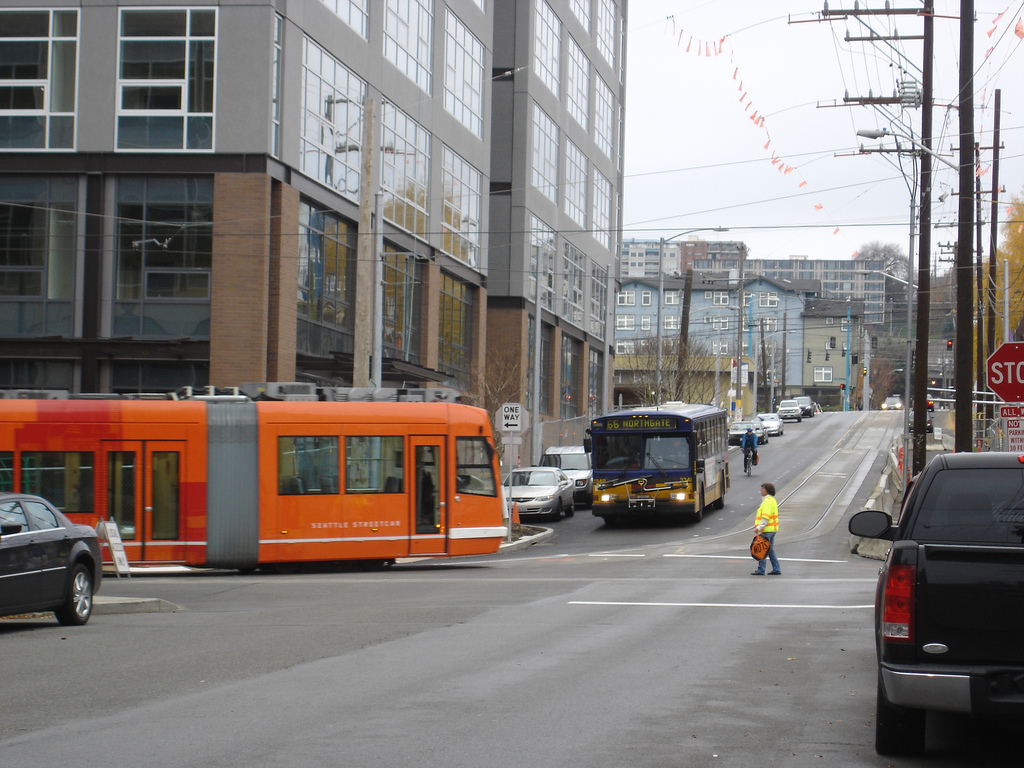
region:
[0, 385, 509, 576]
Orange bus is turning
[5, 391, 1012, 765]
Bus on the road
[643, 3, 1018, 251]
flags hanging from lines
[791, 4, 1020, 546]
Power lines on sidewalk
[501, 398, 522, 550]
A one way sign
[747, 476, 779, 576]
Peron wearing yellow and orange jacket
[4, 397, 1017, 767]
Cars parked in the street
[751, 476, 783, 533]
A woman wearing yellow vest with orange stripes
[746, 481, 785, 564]
A woman holding a stop sign in her right hand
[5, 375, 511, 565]
An orange and white Seattle street car.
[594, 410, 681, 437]
A bus on route 66 enroute to Northgate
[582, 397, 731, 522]
A blue and yellow municipal bus.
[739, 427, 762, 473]
A man in blue riding a bicycle.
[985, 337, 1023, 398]
The edge of a red and white stop sign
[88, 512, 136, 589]
A temporary sign sitting in the street.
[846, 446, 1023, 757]
The rear of a black parked truck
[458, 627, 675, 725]
the street is grey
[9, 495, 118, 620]
a black car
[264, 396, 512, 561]
an orange bus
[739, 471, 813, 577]
a crossing guard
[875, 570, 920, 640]
a back headlight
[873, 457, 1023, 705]
a truck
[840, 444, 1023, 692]
the truck is black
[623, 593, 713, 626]
white line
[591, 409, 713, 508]
a bus in the street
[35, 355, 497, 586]
orange and white bus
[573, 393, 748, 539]
blue and yellow bus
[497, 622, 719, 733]
road is dark grey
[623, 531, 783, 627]
white crosswalk on road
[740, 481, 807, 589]
guard is on road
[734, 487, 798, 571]
yellow and orange shirt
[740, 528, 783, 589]
guard has orange sign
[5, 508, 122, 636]
black car is parked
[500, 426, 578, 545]
row of cars are parked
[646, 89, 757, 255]
grey and white sky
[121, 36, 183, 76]
glass window on building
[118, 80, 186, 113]
glass window on building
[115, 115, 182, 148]
glass window on building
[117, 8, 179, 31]
glass window on building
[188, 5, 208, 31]
glass window on building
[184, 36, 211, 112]
glass window on building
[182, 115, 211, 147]
glass window on building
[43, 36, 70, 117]
glass window on building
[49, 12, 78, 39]
glass window on building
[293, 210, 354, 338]
a window on the building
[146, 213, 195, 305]
a window on the building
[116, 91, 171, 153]
a window on the building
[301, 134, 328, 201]
a window on the building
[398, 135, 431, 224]
a window on the building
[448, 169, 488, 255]
a window on the building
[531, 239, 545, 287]
a window on the building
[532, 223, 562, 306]
a window on the building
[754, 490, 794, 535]
woman is wearing a vest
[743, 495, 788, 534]
vest is yellow and orange in color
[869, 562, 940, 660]
headlight is red in color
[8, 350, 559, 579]
bus is orange in color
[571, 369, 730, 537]
bus is yellow in color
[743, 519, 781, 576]
woman is holding a sign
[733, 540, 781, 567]
sign is orange in color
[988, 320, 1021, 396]
sign is red in color